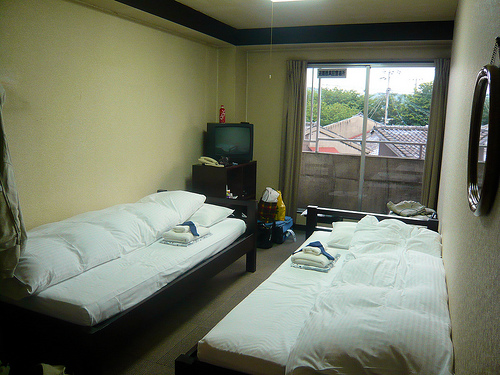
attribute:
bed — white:
[243, 235, 326, 367]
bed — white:
[219, 219, 426, 371]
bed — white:
[185, 245, 390, 371]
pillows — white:
[314, 270, 444, 371]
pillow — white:
[297, 270, 441, 367]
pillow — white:
[300, 286, 442, 373]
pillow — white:
[311, 283, 488, 371]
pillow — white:
[303, 270, 452, 360]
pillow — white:
[311, 286, 439, 366]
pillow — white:
[314, 281, 454, 371]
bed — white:
[234, 240, 329, 343]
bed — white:
[218, 219, 346, 370]